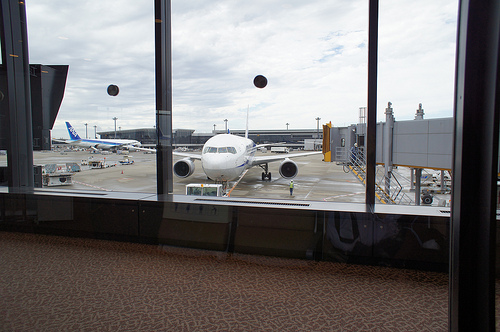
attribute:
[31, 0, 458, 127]
sky — blue 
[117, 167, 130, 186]
cone — road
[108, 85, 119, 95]
magnet — black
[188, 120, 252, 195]
plane — big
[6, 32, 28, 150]
magnet — black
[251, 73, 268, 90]
magnet — black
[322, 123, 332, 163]
trim — yellow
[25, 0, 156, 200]
window — glass, see-through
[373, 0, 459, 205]
window — glass, see-through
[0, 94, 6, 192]
window — glass, see-through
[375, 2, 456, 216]
window — glass, plate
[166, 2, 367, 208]
window — glass, see-through, plate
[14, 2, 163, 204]
window — glass, plate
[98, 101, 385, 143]
building — low, wide, grey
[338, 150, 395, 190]
staris — metal, grey, yellow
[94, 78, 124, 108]
magnet — black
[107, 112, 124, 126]
light — tall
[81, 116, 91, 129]
light — tall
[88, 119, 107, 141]
light — tall